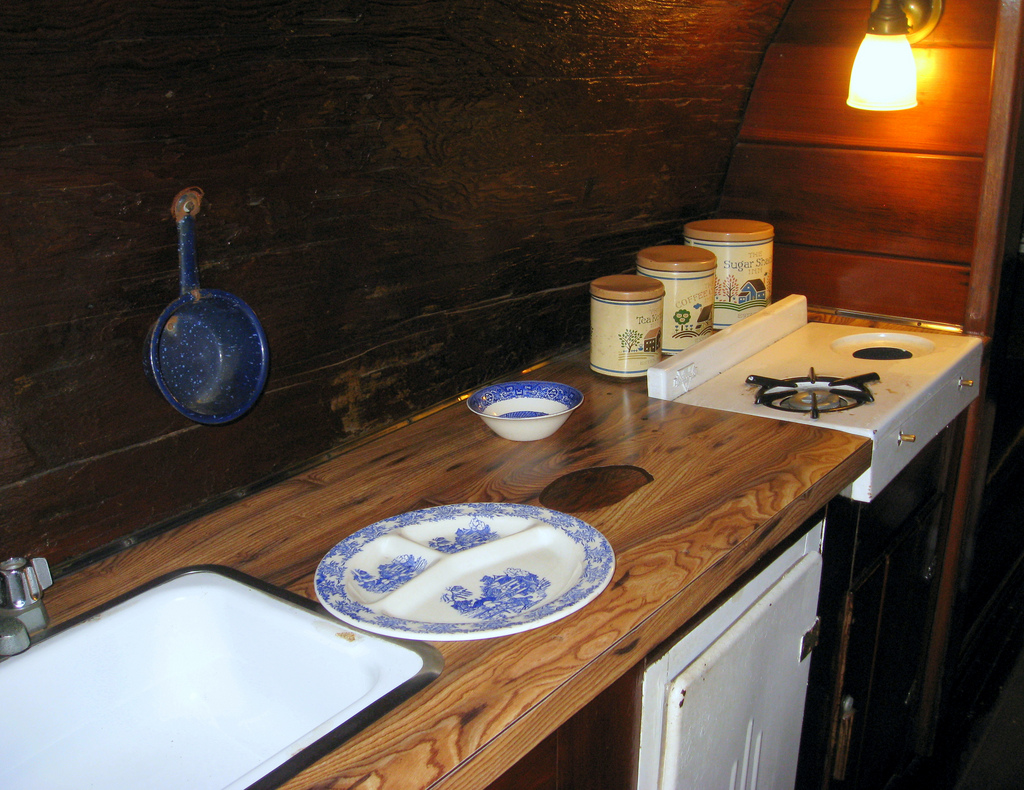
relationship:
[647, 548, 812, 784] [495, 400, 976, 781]
door of cabinet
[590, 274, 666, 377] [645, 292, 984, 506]
canister behind stove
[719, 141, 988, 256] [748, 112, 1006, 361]
panel of wood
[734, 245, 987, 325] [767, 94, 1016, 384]
panel of wood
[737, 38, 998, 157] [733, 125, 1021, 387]
panel of wood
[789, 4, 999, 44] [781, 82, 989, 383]
panel of wood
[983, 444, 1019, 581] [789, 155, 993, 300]
panel of wood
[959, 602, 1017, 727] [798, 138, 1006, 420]
panel of wood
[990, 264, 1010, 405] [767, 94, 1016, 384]
panel of wood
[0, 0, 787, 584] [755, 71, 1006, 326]
panel of wood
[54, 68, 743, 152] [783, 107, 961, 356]
panel of wood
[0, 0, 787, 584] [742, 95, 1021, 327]
panel of wood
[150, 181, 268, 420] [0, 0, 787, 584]
pot hanging on panel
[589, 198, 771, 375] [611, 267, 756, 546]
canisters in kitchen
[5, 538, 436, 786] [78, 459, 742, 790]
sink in kitchen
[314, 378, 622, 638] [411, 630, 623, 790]
dishes on a counter